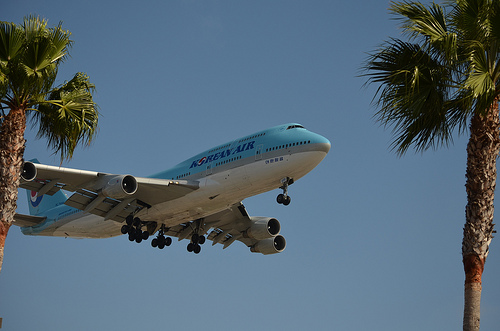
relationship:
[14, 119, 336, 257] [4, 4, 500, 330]
airplane in sky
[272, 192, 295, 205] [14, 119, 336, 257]
wheels on airplane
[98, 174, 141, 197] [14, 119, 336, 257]
engine on airplane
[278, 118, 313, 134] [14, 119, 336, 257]
cockpit on airplane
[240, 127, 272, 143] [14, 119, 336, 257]
windows on airplane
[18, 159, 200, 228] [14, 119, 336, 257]
wing of airplane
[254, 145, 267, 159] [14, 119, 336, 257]
door on airplane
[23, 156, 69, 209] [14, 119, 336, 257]
tail of airplane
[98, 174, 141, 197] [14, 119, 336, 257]
engine of airplane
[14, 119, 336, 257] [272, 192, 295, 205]
airplane has wheels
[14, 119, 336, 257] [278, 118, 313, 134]
airplane has cockpit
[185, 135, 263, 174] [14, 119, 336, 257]
logo on plane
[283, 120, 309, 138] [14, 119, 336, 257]
cockpit on airplane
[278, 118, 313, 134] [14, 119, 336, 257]
cockpit of airplane